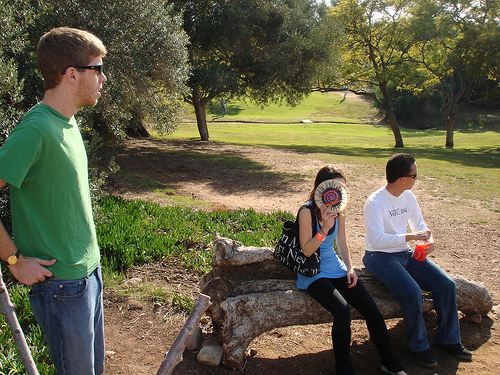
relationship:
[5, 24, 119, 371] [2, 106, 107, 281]
man in shirt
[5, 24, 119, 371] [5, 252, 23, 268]
man wearing wach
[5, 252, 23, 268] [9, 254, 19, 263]
watch has face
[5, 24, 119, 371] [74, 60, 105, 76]
man wearing sunglasses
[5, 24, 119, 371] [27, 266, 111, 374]
man wearing jeans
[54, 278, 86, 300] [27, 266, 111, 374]
rivets on jeans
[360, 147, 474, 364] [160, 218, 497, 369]
man sitting on log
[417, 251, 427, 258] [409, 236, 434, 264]
label on bottle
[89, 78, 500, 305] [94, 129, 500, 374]
grass next to path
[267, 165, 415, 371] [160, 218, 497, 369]
person sits on log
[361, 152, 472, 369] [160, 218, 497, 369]
man sits on log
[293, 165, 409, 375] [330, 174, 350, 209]
person covers face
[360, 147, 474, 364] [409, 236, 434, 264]
man holds bottle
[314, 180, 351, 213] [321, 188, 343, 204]
frisbee with swirls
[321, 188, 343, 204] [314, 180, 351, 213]
swirls on frisbee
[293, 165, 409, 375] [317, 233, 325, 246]
person has braclets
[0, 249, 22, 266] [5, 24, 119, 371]
watch on man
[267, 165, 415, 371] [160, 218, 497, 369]
person sitting on log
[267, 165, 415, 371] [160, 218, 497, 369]
person on log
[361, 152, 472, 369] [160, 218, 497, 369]
man on log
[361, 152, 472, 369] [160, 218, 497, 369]
man sitting on log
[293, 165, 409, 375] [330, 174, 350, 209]
person holding face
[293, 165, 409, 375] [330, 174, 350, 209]
person hiding face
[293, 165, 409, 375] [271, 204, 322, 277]
person holding bag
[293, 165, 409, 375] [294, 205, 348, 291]
person wearing shirt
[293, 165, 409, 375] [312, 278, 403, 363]
person wearing pants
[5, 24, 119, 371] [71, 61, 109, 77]
man wearing sunglasss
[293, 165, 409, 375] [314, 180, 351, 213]
person holding frisbee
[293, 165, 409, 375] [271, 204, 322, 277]
person carrying bag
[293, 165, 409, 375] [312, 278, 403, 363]
person has pants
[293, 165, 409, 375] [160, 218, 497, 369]
person sitting on log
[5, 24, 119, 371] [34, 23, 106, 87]
man has hair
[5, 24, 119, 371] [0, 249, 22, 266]
man wearing watch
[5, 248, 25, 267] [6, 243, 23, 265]
watch has band